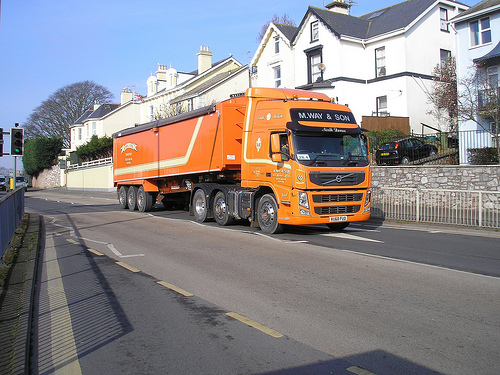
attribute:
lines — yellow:
[131, 246, 259, 363]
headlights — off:
[297, 188, 374, 221]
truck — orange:
[105, 99, 404, 249]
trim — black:
[298, 42, 328, 89]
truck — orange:
[94, 96, 429, 276]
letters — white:
[293, 108, 353, 121]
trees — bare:
[12, 73, 130, 153]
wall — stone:
[363, 162, 498, 227]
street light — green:
[9, 109, 49, 198]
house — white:
[249, 13, 482, 175]